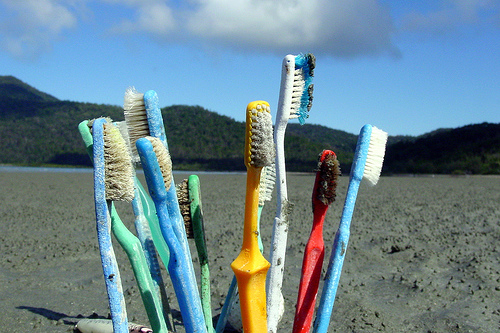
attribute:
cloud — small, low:
[106, 0, 403, 60]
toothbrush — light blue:
[87, 115, 142, 323]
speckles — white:
[107, 253, 124, 320]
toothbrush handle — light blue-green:
[107, 206, 167, 326]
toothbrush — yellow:
[231, 100, 277, 329]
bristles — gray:
[251, 105, 276, 173]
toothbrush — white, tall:
[269, 53, 318, 326]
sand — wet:
[306, 53, 313, 101]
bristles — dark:
[316, 153, 337, 203]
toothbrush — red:
[290, 147, 339, 330]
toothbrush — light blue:
[315, 127, 393, 329]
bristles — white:
[359, 125, 389, 184]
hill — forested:
[1, 77, 496, 169]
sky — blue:
[1, 0, 494, 138]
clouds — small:
[398, 0, 498, 48]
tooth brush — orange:
[230, 98, 277, 328]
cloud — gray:
[128, 5, 410, 64]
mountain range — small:
[0, 74, 495, 173]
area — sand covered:
[0, 161, 494, 329]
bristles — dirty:
[317, 156, 342, 207]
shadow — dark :
[13, 298, 112, 329]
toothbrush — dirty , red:
[300, 147, 345, 330]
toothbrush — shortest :
[170, 159, 235, 329]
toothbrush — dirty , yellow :
[232, 94, 288, 330]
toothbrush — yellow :
[239, 93, 279, 330]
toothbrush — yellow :
[249, 91, 289, 331]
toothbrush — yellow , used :
[236, 97, 286, 330]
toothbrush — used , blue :
[89, 107, 139, 330]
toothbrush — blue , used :
[132, 125, 202, 330]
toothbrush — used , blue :
[122, 82, 216, 307]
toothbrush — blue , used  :
[309, 120, 385, 330]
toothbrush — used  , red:
[298, 144, 332, 328]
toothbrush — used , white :
[276, 40, 318, 330]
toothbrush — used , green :
[80, 123, 174, 328]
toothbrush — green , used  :
[100, 116, 216, 326]